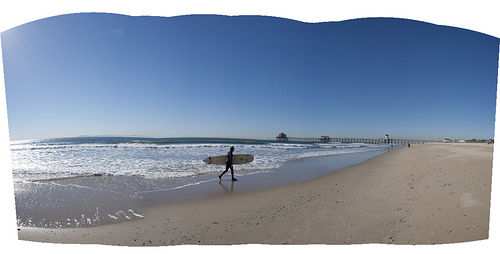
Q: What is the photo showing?
A: It is showing a beach.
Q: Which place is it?
A: It is a beach.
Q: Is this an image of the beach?
A: Yes, it is showing the beach.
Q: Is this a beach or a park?
A: It is a beach.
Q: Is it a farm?
A: No, it is a beach.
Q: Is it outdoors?
A: Yes, it is outdoors.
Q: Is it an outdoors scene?
A: Yes, it is outdoors.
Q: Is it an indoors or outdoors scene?
A: It is outdoors.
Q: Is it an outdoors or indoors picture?
A: It is outdoors.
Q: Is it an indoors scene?
A: No, it is outdoors.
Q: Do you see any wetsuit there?
A: Yes, there is a wetsuit.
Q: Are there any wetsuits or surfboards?
A: Yes, there is a wetsuit.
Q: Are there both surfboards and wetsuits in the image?
A: Yes, there are both a wetsuit and a surfboard.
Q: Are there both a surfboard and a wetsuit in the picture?
A: Yes, there are both a wetsuit and a surfboard.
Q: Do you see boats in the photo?
A: No, there are no boats.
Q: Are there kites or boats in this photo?
A: No, there are no boats or kites.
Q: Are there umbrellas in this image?
A: No, there are no umbrellas.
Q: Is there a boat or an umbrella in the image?
A: No, there are no umbrellas or boats.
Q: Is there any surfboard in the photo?
A: Yes, there is a surfboard.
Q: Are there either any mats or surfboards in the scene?
A: Yes, there is a surfboard.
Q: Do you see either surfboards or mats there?
A: Yes, there is a surfboard.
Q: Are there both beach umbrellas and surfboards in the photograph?
A: No, there is a surfboard but no beach umbrellas.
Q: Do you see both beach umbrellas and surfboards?
A: No, there is a surfboard but no beach umbrellas.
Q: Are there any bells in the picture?
A: No, there are no bells.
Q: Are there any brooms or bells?
A: No, there are no bells or brooms.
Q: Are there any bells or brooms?
A: No, there are no bells or brooms.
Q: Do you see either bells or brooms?
A: No, there are no bells or brooms.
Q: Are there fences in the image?
A: No, there are no fences.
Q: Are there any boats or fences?
A: No, there are no fences or boats.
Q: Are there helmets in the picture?
A: No, there are no helmets.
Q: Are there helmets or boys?
A: No, there are no helmets or boys.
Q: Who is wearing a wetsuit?
A: The man is wearing a wetsuit.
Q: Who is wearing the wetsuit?
A: The man is wearing a wetsuit.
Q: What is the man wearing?
A: The man is wearing a wetsuit.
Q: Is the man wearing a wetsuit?
A: Yes, the man is wearing a wetsuit.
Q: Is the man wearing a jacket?
A: No, the man is wearing a wetsuit.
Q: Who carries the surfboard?
A: The man carries the surfboard.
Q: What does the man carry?
A: The man carries a surfboard.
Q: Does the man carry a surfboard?
A: Yes, the man carries a surfboard.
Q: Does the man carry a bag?
A: No, the man carries a surfboard.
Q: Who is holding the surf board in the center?
A: The man is holding the surf board.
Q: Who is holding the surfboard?
A: The man is holding the surf board.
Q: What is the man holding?
A: The man is holding the surfboard.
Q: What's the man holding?
A: The man is holding the surfboard.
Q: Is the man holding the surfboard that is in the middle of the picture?
A: Yes, the man is holding the surfboard.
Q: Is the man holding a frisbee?
A: No, the man is holding the surfboard.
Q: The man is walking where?
A: The man is walking on the beach.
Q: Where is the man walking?
A: The man is walking on the beach.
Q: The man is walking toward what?
A: The man is walking toward the beach.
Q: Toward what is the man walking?
A: The man is walking toward the beach.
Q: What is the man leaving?
A: The man is leaving the ocean.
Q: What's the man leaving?
A: The man is leaving the ocean.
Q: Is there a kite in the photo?
A: No, there are no kites.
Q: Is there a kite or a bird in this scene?
A: No, there are no kites or birds.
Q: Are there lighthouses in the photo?
A: No, there are no lighthouses.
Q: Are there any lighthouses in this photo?
A: No, there are no lighthouses.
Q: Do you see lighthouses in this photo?
A: No, there are no lighthouses.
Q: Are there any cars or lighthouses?
A: No, there are no lighthouses or cars.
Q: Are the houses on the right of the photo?
A: Yes, the houses are on the right of the image.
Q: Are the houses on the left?
A: No, the houses are on the right of the image.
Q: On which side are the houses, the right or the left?
A: The houses are on the right of the image.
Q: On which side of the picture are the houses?
A: The houses are on the right of the image.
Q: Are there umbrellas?
A: No, there are no umbrellas.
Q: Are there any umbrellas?
A: No, there are no umbrellas.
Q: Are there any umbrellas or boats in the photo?
A: No, there are no umbrellas or boats.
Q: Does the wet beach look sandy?
A: Yes, the beach is sandy.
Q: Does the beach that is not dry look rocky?
A: No, the beach is sandy.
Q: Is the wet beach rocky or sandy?
A: The beach is sandy.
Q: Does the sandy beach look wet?
A: Yes, the beach is wet.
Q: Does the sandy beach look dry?
A: No, the beach is wet.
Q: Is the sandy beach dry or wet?
A: The beach is wet.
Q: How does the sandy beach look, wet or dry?
A: The beach is wet.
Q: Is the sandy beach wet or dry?
A: The beach is wet.